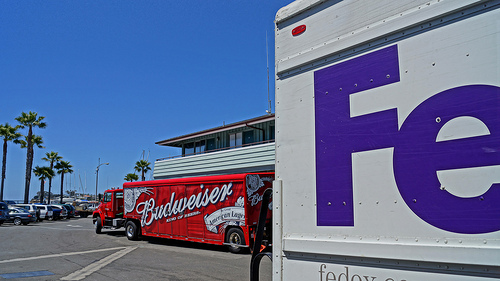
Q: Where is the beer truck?
A: Parking lot?.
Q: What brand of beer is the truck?
A: Busweiser.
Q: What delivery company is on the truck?
A: Fedex.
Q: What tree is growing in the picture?
A: Palm.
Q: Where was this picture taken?
A: Parking lot.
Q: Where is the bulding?
A: Behind the truck.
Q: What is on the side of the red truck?
A: Lettering.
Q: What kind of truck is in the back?
A: Commercial truck.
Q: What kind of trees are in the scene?
A: Palm trees.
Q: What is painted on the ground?
A: Lines.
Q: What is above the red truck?
A: A building.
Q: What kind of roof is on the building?
A: Overhang.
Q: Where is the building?
A: Behind Budweiser truck.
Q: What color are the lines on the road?
A: White.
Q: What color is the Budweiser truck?
A: Red and white.